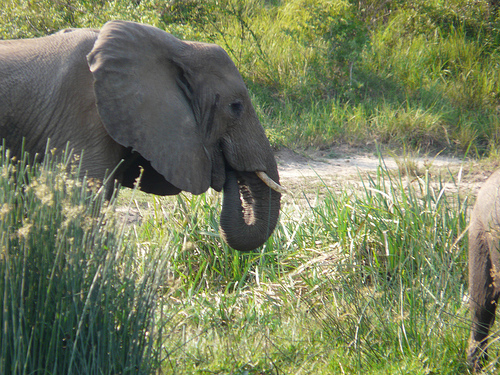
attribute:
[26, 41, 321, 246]
elephant — eating, gray, wrinkled, grey, small, large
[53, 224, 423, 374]
grass — tall, green, dry, patch, long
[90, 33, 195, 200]
ears — wide, big, large, floppy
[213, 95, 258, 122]
eye — black, small, open, elephant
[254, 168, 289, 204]
tusks — white, short, tan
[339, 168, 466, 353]
weeds — tall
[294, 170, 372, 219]
dirt — road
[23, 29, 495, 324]
photo — outdoors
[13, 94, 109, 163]
skin — wrinkled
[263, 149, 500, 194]
path — grassless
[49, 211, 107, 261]
buds — purple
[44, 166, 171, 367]
shrub — small